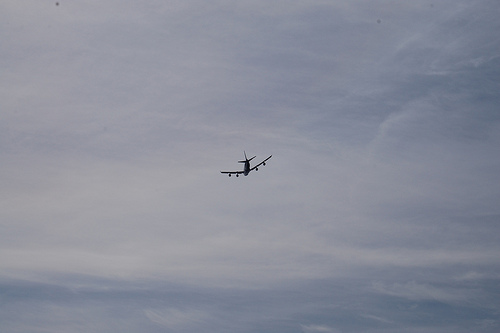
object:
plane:
[219, 150, 272, 177]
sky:
[0, 1, 499, 331]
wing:
[250, 155, 272, 171]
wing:
[221, 170, 244, 174]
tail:
[238, 150, 257, 163]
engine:
[262, 162, 266, 166]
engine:
[255, 168, 258, 172]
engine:
[236, 173, 239, 176]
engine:
[229, 174, 232, 177]